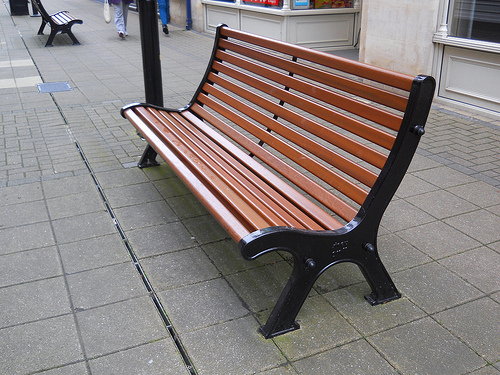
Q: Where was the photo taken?
A: It was taken at the sidewalk.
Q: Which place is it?
A: It is a sidewalk.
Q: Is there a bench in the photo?
A: Yes, there is a bench.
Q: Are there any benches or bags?
A: Yes, there is a bench.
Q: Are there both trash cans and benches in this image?
A: No, there is a bench but no trash cans.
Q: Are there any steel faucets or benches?
A: Yes, there is a steel bench.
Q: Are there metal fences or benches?
A: Yes, there is a metal bench.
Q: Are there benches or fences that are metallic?
A: Yes, the bench is metallic.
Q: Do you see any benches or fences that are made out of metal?
A: Yes, the bench is made of metal.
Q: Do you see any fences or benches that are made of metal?
A: Yes, the bench is made of metal.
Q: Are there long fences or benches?
A: Yes, there is a long bench.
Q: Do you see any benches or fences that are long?
A: Yes, the bench is long.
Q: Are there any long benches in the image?
A: Yes, there is a long bench.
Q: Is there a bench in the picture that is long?
A: Yes, there is a bench that is long.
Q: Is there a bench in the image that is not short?
A: Yes, there is a long bench.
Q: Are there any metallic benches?
A: Yes, there is a metal bench.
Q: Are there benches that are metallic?
A: Yes, there is a bench that is metallic.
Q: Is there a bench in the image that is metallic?
A: Yes, there is a bench that is metallic.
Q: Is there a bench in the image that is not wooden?
A: Yes, there is a metallic bench.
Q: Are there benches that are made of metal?
A: Yes, there is a bench that is made of metal.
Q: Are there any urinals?
A: No, there are no urinals.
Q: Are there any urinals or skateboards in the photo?
A: No, there are no urinals or skateboards.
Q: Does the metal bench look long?
A: Yes, the bench is long.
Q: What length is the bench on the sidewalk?
A: The bench is long.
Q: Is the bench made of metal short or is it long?
A: The bench is long.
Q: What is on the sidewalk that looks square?
A: The bench is on the sidewalk.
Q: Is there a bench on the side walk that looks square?
A: Yes, there is a bench on the sidewalk.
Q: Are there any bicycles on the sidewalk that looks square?
A: No, there is a bench on the side walk.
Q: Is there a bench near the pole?
A: Yes, there is a bench near the pole.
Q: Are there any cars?
A: No, there are no cars.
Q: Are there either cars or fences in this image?
A: No, there are no cars or fences.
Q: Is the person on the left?
A: Yes, the person is on the left of the image.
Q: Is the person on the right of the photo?
A: No, the person is on the left of the image.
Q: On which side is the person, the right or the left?
A: The person is on the left of the image.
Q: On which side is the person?
A: The person is on the left of the image.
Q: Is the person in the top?
A: Yes, the person is in the top of the image.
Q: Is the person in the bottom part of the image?
A: No, the person is in the top of the image.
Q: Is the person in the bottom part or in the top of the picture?
A: The person is in the top of the image.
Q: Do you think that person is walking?
A: Yes, the person is walking.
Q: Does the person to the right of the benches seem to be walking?
A: Yes, the person is walking.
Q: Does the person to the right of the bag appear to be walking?
A: Yes, the person is walking.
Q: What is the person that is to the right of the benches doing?
A: The person is walking.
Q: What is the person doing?
A: The person is walking.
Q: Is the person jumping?
A: No, the person is walking.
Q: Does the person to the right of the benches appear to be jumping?
A: No, the person is walking.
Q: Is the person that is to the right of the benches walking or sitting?
A: The person is walking.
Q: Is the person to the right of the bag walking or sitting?
A: The person is walking.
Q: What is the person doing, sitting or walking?
A: The person is walking.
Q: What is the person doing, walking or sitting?
A: The person is walking.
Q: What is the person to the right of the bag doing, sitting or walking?
A: The person is walking.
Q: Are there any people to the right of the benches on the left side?
A: Yes, there is a person to the right of the benches.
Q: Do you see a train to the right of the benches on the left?
A: No, there is a person to the right of the benches.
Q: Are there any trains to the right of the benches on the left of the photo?
A: No, there is a person to the right of the benches.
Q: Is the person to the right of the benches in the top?
A: Yes, the person is to the right of the benches.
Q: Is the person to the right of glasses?
A: No, the person is to the right of the benches.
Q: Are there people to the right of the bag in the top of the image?
A: Yes, there is a person to the right of the bag.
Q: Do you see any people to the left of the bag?
A: No, the person is to the right of the bag.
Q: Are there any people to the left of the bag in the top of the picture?
A: No, the person is to the right of the bag.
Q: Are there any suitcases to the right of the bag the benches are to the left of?
A: No, there is a person to the right of the bag.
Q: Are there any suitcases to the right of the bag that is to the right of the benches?
A: No, there is a person to the right of the bag.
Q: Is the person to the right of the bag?
A: Yes, the person is to the right of the bag.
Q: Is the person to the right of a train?
A: No, the person is to the right of the bag.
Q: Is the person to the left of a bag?
A: No, the person is to the right of a bag.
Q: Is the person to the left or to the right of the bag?
A: The person is to the right of the bag.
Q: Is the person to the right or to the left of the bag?
A: The person is to the right of the bag.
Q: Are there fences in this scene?
A: No, there are no fences.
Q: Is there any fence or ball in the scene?
A: No, there are no fences or balls.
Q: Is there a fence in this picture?
A: No, there are no fences.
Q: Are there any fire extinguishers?
A: No, there are no fire extinguishers.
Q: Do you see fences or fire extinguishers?
A: No, there are no fire extinguishers or fences.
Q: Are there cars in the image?
A: No, there are no cars.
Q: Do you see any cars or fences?
A: No, there are no cars or fences.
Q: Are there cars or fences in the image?
A: No, there are no cars or fences.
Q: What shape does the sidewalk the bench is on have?
A: The sidewalk has square shape.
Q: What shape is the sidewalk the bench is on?
A: The sidewalk is square.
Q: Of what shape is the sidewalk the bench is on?
A: The sidewalk is square.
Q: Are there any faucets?
A: No, there are no faucets.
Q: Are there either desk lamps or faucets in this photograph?
A: No, there are no faucets or desk lamps.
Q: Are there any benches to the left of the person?
A: Yes, there are benches to the left of the person.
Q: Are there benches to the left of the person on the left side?
A: Yes, there are benches to the left of the person.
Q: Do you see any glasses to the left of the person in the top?
A: No, there are benches to the left of the person.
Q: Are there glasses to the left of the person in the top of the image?
A: No, there are benches to the left of the person.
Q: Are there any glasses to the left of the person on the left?
A: No, there are benches to the left of the person.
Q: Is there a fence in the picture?
A: No, there are no fences.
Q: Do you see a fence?
A: No, there are no fences.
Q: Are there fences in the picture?
A: No, there are no fences.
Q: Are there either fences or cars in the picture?
A: No, there are no fences or cars.